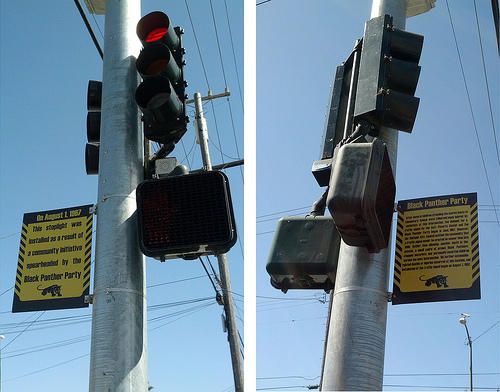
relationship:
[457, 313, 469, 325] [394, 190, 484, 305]
light under sign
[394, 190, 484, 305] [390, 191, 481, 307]
sign with more background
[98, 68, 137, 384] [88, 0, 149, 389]
shadow on pole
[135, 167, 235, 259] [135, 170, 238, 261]
signal stating signal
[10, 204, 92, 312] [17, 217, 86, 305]
sign with a background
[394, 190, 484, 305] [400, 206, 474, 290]
sign with a background